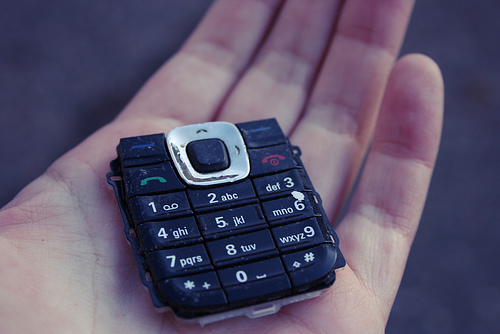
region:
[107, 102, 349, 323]
a keypad in the hand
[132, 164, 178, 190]
a green phone on a button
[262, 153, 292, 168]
a red phone on the button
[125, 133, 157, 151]
a blue line on the button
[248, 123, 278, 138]
a blue line on the right button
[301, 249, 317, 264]
a number sign on the bottom button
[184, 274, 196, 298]
an asterisk sign on the bottom left button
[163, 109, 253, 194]
silver arrows around the center button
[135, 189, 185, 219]
a 1 under the green phone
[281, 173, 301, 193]
a 3 under the red phone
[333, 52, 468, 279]
a pinky finger on a hand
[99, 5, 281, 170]
the index finger on a hand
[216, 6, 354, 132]
the middle finger on a hand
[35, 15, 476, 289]
the hand of a person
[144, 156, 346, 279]
buttons on part of a phone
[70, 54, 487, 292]
a hand holding part of a phone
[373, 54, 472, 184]
the tip of a finger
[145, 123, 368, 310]
numbers on part of a broken phone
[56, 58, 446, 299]
the palm of a hand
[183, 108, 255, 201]
a black button on part of a phone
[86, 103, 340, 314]
the keypad is black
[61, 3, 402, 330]
keypad on person's hand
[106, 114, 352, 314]
a broken cell phone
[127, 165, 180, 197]
the call button on a cell phone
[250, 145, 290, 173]
the end button on a cell phone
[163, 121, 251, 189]
analog directional keypad on a phone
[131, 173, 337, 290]
a keypad on a cell phone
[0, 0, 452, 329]
a broken cell phone in a hand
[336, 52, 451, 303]
a pinky finger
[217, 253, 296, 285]
the 0 button on a key pad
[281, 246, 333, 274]
the pound button on a key pad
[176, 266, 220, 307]
the star button on a key pad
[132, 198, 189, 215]
a button with the number one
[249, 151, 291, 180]
a red phone on button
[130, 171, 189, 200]
a green phone button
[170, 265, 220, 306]
an asterick on button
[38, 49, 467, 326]
a part of a cell phone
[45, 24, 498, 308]
a hand holding something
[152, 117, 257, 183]
directional arrows on a silver area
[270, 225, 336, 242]
wxyz and 9 on this button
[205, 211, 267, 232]
5 and jkl on this buton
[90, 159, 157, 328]
a metal flange on the side